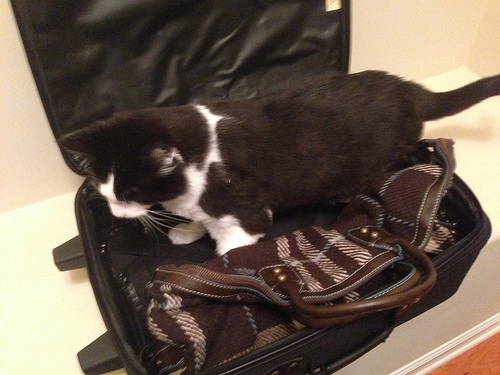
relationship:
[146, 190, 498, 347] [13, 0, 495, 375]
purse inside suit case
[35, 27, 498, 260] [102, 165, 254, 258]
cat has white part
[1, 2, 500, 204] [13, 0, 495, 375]
wall behind suit case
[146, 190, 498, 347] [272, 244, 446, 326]
purse has handle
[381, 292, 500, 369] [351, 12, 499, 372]
wood on side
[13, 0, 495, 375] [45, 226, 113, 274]
suit case has leg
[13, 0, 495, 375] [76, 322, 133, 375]
suit case has leg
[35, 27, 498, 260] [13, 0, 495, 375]
cat in suit case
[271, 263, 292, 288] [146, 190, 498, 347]
button on purse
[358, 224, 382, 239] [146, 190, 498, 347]
button on purse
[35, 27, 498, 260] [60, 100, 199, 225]
cat has head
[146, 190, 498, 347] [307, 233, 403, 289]
bag has flap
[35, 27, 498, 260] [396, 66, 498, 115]
cat has tail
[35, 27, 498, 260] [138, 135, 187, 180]
cat has ear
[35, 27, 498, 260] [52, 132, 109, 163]
cat has ear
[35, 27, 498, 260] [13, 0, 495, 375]
cat standing in suit case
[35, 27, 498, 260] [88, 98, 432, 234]
cat has hair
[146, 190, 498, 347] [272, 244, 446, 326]
purse has strap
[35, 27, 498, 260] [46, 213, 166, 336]
cat looking down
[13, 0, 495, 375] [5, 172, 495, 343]
luggage on table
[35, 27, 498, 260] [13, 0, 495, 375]
cat inside suit case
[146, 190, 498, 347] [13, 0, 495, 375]
purse in suit case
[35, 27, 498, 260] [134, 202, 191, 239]
cat has whiskers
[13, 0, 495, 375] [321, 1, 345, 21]
suit case has tag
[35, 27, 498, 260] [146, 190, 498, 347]
cat next to bag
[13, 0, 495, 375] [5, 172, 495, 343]
suit case on top of dresser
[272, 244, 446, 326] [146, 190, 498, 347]
handle on bag